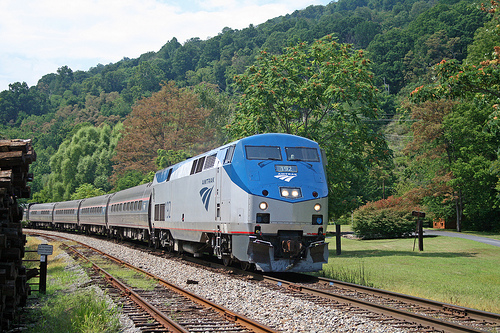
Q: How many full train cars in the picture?
A: Five.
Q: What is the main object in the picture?
A: Train.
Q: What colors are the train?
A: Blue and silver.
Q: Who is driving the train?
A: Engineer.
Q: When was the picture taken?
A: Daytime.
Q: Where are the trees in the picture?
A: On the right side.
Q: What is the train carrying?
A: Passengers.